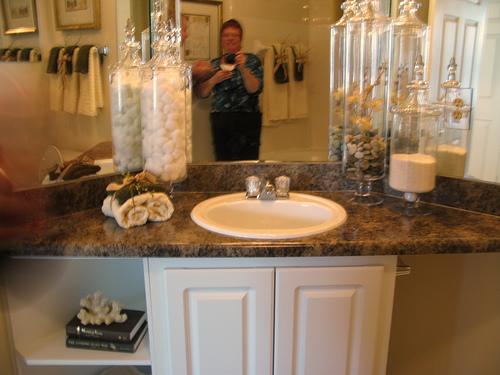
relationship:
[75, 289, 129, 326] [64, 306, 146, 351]
figurine on top of books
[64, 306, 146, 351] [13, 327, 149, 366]
books on shelf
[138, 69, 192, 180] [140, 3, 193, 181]
cotton balls in jar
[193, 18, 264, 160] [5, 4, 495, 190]
lady reflected in mirror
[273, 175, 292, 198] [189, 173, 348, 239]
knob on sink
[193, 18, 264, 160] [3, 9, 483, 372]
lady standing bathroom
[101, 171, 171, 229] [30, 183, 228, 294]
towel on counter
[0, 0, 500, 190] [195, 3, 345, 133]
mirror on walls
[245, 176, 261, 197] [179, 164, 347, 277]
knob on sink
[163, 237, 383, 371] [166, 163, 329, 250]
cupboards under sink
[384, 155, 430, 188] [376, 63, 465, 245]
soap in jar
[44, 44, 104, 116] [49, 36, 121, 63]
towels in rack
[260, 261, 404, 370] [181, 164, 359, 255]
drawer under sink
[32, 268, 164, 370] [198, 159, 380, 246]
shelf under counter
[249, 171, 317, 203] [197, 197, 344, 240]
faucet on sink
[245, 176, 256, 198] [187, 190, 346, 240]
knob of sink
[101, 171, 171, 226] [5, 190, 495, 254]
towel on counter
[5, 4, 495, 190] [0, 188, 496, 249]
mirror on counter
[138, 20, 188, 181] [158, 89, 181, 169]
jar of cotton balls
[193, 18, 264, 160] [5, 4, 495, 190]
lady in mirror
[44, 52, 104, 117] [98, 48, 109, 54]
towels hanging on rack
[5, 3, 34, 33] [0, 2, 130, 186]
picture hanging on wall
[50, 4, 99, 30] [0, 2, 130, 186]
picture hanging on wall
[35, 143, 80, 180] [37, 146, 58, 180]
toilet with seat